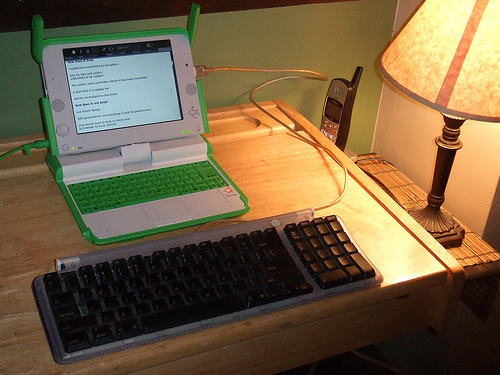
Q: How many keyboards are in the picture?
A: Two.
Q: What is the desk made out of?
A: Wood.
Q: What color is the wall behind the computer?
A: Green.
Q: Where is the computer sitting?
A: On the desk.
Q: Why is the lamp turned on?
A: Need light.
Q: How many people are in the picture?
A: None.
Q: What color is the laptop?
A: Green.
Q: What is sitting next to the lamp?
A: A portable phone.